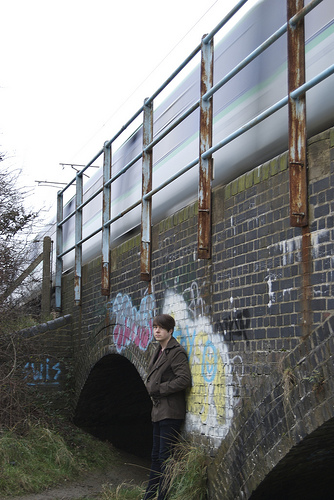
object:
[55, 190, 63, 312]
rail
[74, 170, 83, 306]
rail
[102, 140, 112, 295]
rail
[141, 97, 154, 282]
rail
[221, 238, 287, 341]
brick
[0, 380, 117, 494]
grass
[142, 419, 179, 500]
pants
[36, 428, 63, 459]
grass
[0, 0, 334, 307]
train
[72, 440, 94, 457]
weeds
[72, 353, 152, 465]
tunnel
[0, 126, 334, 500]
bridge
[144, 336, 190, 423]
coat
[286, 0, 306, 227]
pole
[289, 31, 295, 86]
rust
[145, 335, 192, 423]
brown coat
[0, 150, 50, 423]
tree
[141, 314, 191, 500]
boy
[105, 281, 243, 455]
graffiti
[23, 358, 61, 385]
graffiti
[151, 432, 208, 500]
grass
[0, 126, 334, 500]
wall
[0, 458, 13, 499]
grass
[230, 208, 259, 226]
ciderblock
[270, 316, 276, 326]
ciderblock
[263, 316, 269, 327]
ciderblock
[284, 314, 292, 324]
ciderblock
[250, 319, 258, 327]
ciderblock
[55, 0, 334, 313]
guard rails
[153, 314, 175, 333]
hair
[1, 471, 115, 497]
ground